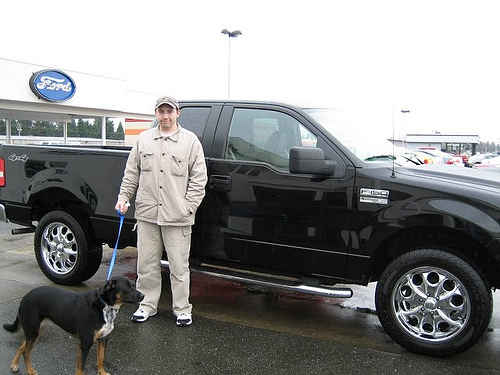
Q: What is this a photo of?
A: A man dog and truck.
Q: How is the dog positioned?
A: In front of the man.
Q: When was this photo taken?
A: During the daytime.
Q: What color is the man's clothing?
A: Khaki.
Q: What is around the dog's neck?
A: A leash.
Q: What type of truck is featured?
A: A black Ford F-150.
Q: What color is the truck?
A: Black.